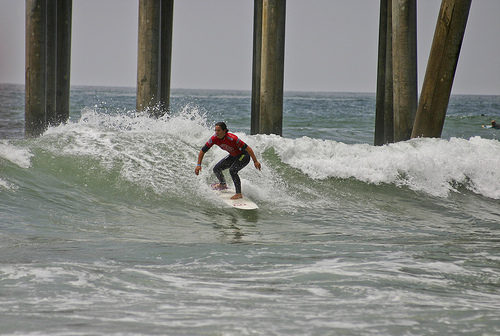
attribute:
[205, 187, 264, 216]
surfboard — white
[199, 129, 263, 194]
wetsuit — red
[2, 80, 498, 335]
water — blue, green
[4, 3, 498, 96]
sky — blue grey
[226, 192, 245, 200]
foot — bare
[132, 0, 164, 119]
support — brown, wood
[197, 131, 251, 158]
shirt — red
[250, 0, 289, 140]
pillar — brown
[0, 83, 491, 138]
water — blue, still, distant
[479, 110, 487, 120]
swimmer — distant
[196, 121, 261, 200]
surfer — experienced, female, riding, surfing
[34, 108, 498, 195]
waves — breaking, white, crashing